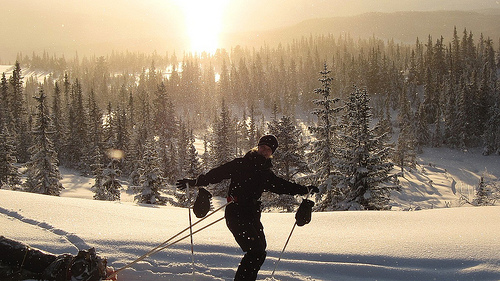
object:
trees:
[419, 27, 500, 154]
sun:
[174, 4, 226, 44]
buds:
[333, 209, 478, 259]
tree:
[128, 139, 169, 203]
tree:
[327, 89, 400, 212]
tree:
[474, 175, 488, 204]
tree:
[88, 150, 110, 200]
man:
[174, 133, 319, 280]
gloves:
[192, 187, 213, 218]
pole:
[100, 200, 234, 281]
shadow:
[97, 236, 499, 280]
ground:
[2, 64, 499, 281]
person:
[172, 135, 322, 281]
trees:
[23, 50, 211, 102]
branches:
[370, 144, 401, 193]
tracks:
[124, 233, 234, 278]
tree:
[23, 81, 65, 193]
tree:
[293, 59, 349, 209]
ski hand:
[304, 184, 321, 194]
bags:
[193, 186, 212, 218]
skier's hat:
[258, 134, 279, 154]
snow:
[0, 45, 499, 281]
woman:
[176, 134, 321, 281]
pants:
[223, 217, 267, 281]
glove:
[294, 200, 314, 227]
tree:
[82, 85, 112, 178]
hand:
[175, 177, 195, 192]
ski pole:
[184, 182, 195, 281]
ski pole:
[264, 187, 317, 280]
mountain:
[0, 0, 500, 281]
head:
[258, 135, 279, 159]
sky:
[0, 0, 499, 85]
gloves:
[174, 178, 196, 190]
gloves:
[305, 185, 320, 194]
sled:
[0, 237, 122, 281]